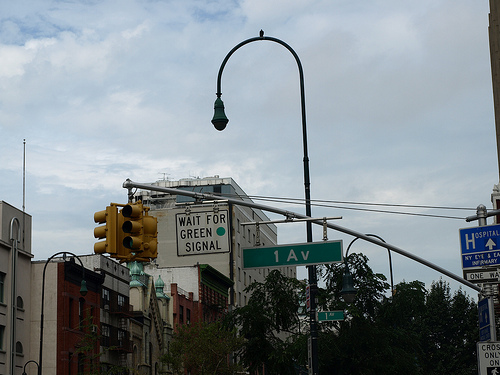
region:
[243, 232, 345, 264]
Green and white street sign for 1 Av.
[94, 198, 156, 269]
Two traffic lights one with green light on.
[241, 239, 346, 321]
Two street signs for same street number.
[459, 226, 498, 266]
Sign for hospital points straight ahead.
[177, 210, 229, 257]
White sign says WAIT FOR GREEN SIGNAL.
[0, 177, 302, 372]
All buildings have multi stories.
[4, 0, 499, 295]
The sky is mostly cloudy.with blue spots in upper left.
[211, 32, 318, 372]
Curved pole has street light on end.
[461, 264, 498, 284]
One way sign points to the right.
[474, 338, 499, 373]
Sign instructing pedestrians about crossing street.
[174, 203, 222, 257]
black and white sign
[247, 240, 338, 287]
green and white sign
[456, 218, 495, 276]
blue and white sign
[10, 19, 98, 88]
white cloud in blue sky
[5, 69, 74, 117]
white cloud in blue sky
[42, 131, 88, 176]
white cloud in blue sky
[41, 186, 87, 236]
white cloud in blue sky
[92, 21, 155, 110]
white cloud in blue sky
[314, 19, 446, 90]
white cloud in blue sky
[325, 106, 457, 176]
white cloud in blue sky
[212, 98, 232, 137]
street light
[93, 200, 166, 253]
yellow signal lights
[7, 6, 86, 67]
white clouds in blue sky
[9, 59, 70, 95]
white clouds in blue sky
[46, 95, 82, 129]
white clouds in blue sky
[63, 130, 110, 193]
white clouds in blue sky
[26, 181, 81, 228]
white clouds in blue sky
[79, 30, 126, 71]
white clouds in blue sky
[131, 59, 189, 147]
white clouds in blue sky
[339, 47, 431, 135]
white clouds in blue sky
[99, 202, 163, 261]
yellow signal light hanging from pole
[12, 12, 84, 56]
white clouds on blue sky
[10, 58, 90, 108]
white clouds on blue sky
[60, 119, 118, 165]
white clouds on blue sky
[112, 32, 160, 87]
white clouds on blue sky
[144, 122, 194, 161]
white clouds on blue sky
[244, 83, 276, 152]
white clouds on blue sky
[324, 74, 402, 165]
white clouds on blue sky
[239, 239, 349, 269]
1 Av street sign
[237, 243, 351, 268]
green street sign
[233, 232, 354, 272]
green street sign on post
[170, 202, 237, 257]
white and black street sign with green dot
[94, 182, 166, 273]
yellow traffic lights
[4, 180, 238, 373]
buildings across the street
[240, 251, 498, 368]
trees in the distance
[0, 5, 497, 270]
cloudy sky over town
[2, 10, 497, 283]
cloudy sky over city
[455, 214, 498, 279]
blue sign on post